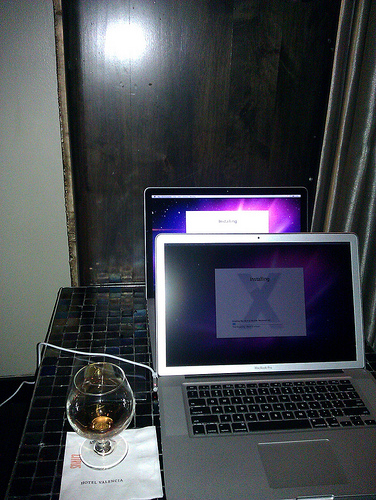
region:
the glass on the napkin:
[72, 359, 142, 474]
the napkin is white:
[51, 431, 165, 496]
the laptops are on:
[146, 172, 372, 496]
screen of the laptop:
[149, 237, 364, 369]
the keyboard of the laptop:
[185, 378, 371, 433]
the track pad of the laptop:
[250, 435, 355, 493]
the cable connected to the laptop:
[33, 332, 153, 387]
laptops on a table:
[86, 157, 315, 486]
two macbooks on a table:
[68, 181, 316, 474]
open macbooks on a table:
[121, 198, 360, 496]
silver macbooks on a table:
[94, 196, 333, 473]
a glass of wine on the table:
[43, 365, 168, 482]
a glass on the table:
[48, 365, 165, 477]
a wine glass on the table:
[46, 379, 153, 491]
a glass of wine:
[33, 352, 137, 488]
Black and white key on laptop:
[187, 420, 207, 435]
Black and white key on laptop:
[187, 399, 209, 423]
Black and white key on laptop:
[201, 387, 226, 400]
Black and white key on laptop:
[203, 398, 235, 413]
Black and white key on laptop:
[218, 408, 251, 432]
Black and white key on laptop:
[226, 388, 259, 402]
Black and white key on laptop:
[242, 403, 261, 415]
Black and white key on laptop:
[266, 378, 307, 416]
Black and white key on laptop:
[315, 382, 345, 400]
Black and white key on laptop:
[291, 396, 332, 418]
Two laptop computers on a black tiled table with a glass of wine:
[61, 173, 371, 496]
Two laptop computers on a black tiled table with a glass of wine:
[58, 174, 370, 491]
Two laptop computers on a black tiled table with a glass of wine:
[61, 180, 369, 490]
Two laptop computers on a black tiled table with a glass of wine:
[62, 181, 374, 489]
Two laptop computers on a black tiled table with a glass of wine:
[60, 174, 370, 485]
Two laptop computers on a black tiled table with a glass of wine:
[58, 180, 372, 485]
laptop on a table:
[142, 226, 374, 498]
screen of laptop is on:
[143, 224, 370, 380]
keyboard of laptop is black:
[176, 372, 374, 437]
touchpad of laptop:
[252, 432, 354, 495]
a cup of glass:
[58, 360, 141, 469]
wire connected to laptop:
[125, 346, 167, 399]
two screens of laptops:
[132, 174, 372, 383]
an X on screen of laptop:
[205, 260, 309, 340]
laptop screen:
[157, 240, 360, 372]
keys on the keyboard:
[209, 386, 343, 428]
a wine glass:
[55, 360, 143, 437]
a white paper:
[131, 456, 152, 495]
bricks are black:
[26, 436, 63, 477]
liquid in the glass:
[74, 405, 113, 431]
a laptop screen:
[146, 190, 298, 231]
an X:
[235, 268, 284, 328]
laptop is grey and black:
[165, 235, 373, 495]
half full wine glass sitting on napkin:
[62, 360, 163, 498]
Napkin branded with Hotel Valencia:
[64, 431, 164, 498]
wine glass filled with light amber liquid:
[65, 359, 132, 465]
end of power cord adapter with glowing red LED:
[149, 368, 158, 390]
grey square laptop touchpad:
[252, 435, 350, 483]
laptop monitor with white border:
[154, 231, 360, 368]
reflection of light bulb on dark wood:
[90, 7, 152, 67]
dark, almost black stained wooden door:
[217, 22, 314, 169]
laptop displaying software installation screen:
[151, 232, 374, 494]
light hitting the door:
[63, 7, 193, 121]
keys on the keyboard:
[171, 363, 371, 470]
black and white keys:
[174, 351, 358, 452]